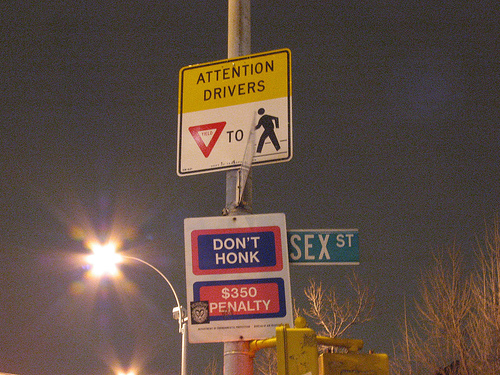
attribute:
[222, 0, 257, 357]
pole — gray, white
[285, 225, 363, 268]
sign — green, white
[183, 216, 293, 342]
sign — blue, red, white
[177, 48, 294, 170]
sign — yellow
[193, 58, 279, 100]
letters — black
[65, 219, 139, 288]
light — bright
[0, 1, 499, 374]
sky — dark, gray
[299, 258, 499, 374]
branches — bare, brown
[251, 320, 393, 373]
signals — yellow